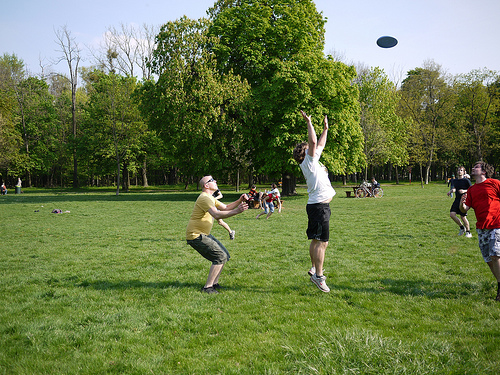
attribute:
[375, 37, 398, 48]
frisbee — blue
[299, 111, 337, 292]
man — jumping, playing, reaching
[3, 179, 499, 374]
ground — short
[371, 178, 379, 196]
person — sitting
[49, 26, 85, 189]
tree — bare, leafless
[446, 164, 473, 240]
person — in motion, all black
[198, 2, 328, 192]
tree — large, green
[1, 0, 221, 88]
sky — blue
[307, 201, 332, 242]
shorts — black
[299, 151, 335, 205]
shirt — white